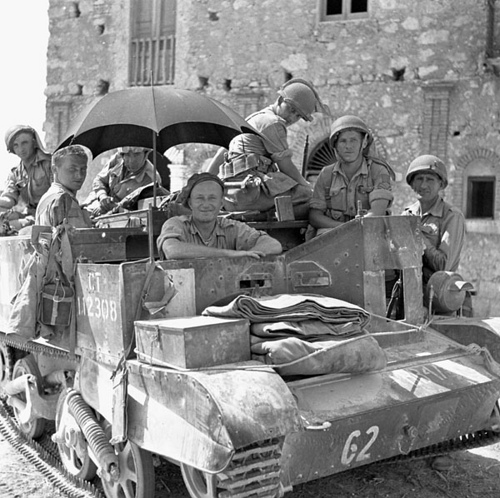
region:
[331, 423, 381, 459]
white lettering on the front of the tank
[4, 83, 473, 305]
several soldiers riding on a tank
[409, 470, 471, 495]
grey dirt of the ground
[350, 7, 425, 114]
grey stone wall of the building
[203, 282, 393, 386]
blankets sitting on top of the tank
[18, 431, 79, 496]
metal tracks of the tank on the ground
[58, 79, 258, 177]
a black umbrella over the tank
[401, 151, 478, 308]
a man standing next to the tank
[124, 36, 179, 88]
wood bars over the window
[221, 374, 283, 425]
grey metal surface of the tank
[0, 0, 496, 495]
A group of men are in a tank.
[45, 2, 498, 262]
A building is next to the tank.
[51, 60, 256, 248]
An umbrella is on the tank.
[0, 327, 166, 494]
The tank treads move around the wheels on the tank.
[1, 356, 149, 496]
Three wheels are visible on the tank.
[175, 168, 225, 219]
The man is wearing a hat.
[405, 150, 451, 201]
The man is wearing a helmet.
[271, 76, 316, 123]
Another man wearing a helmet.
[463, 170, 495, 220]
A window on the building.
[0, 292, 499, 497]
The tank is on a dirt road.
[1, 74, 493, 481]
the soilders ride on the tank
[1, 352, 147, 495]
the wheels of the tank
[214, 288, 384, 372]
the blankets on the front of the tank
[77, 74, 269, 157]
the black umbrella on the tank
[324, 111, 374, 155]
the helmet on the head of the soilder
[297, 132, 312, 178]
the barrel of the soilders gun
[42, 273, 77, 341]
the canteen hanging over the side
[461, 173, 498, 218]
the open window on the building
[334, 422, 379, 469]
the white lettering on the fron of the tank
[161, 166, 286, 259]
the man under the umbrella smiling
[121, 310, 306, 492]
the tank is old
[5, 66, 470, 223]
the soldiers are in a tank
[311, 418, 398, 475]
the tank has a number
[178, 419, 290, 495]
it operates on chains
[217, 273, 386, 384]
a tent is on the front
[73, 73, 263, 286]
a black umbrella is on the tank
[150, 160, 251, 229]
the man is wearing a beret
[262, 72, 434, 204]
the soldiers are wearing helmets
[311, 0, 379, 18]
the wall has no glasses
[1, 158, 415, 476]
the tank is old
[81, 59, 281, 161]
the umbrella i black in color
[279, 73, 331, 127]
the helmet is grey in color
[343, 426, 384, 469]
c2 is on the metal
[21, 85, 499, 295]
the soldiers are posing for the camera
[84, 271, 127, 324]
wriitng is on the side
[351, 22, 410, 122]
the wall is grey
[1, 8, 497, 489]
the photo is black and white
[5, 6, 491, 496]
photo was taken during the day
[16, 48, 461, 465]
the officers are on the tank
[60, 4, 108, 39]
holes are on the building